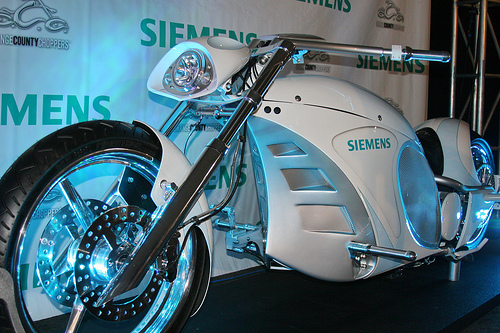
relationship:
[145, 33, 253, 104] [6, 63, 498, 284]
headlight on bike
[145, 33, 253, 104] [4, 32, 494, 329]
headlight on bike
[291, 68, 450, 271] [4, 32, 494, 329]
tank on bike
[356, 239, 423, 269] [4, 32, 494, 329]
pedal on bike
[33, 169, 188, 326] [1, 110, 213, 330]
spokes on front wheel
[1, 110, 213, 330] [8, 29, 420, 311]
front wheel on motorcycle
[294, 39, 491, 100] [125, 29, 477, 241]
handlebars on motorcycle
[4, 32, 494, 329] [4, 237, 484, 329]
bike on platform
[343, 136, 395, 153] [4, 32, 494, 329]
logo on bike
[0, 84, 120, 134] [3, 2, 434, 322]
logo on wall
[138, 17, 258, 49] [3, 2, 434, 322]
logo on wall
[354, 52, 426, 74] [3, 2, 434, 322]
logo on wall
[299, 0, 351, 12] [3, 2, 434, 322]
logo on wall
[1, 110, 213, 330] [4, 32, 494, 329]
front wheel of bike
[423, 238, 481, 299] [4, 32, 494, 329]
stand on bike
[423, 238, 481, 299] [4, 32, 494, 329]
stand of bike